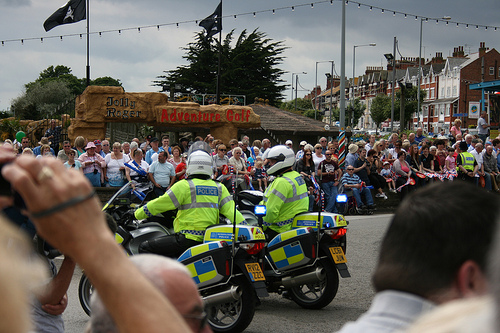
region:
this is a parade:
[91, 93, 418, 295]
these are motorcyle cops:
[158, 164, 378, 316]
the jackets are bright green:
[157, 165, 267, 222]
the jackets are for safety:
[155, 160, 265, 280]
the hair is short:
[362, 205, 464, 323]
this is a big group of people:
[295, 125, 430, 202]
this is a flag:
[29, 0, 93, 45]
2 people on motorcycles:
[61, 113, 371, 327]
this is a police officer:
[129, 128, 265, 271]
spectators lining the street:
[39, 75, 489, 232]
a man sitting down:
[335, 158, 382, 205]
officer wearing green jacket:
[138, 149, 273, 262]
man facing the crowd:
[450, 131, 485, 183]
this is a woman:
[299, 143, 316, 172]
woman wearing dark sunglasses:
[302, 150, 317, 163]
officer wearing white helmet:
[171, 135, 224, 185]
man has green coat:
[131, 177, 232, 249]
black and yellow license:
[227, 245, 269, 279]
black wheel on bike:
[192, 283, 247, 325]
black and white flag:
[27, 5, 101, 35]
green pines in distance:
[177, 37, 299, 109]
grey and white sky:
[265, 0, 345, 72]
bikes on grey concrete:
[334, 200, 418, 274]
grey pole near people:
[318, 14, 375, 165]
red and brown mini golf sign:
[78, 75, 306, 147]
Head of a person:
[255, 140, 297, 185]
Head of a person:
[175, 145, 215, 185]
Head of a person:
[131, 144, 147, 162]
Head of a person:
[110, 141, 123, 154]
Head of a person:
[79, 139, 98, 157]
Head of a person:
[99, 137, 113, 153]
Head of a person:
[341, 161, 360, 177]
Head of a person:
[323, 146, 334, 161]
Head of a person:
[383, 157, 395, 171]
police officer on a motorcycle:
[77, 147, 264, 332]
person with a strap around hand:
[0, 142, 190, 332]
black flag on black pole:
[198, 0, 226, 102]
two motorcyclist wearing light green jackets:
[131, 144, 308, 274]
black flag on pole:
[42, 1, 90, 83]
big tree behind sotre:
[161, 24, 287, 104]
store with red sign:
[67, 83, 347, 148]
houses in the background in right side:
[298, 44, 499, 136]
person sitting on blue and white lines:
[341, 162, 377, 212]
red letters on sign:
[155, 106, 255, 123]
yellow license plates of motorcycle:
[244, 241, 347, 283]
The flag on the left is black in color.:
[44, 0, 87, 31]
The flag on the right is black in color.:
[198, 0, 225, 31]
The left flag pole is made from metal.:
[82, 0, 92, 85]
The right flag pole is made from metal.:
[218, 29, 223, 106]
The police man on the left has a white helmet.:
[182, 141, 217, 180]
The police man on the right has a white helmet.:
[262, 144, 298, 176]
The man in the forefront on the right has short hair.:
[370, 180, 497, 300]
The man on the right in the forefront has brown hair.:
[372, 180, 497, 297]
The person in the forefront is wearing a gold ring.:
[2, 157, 117, 244]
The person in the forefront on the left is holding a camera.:
[0, 152, 186, 330]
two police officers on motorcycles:
[76, 130, 350, 327]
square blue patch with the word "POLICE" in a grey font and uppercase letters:
[190, 181, 220, 198]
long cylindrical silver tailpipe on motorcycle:
[200, 283, 246, 307]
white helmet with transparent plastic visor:
[183, 138, 215, 177]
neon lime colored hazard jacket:
[136, 176, 247, 239]